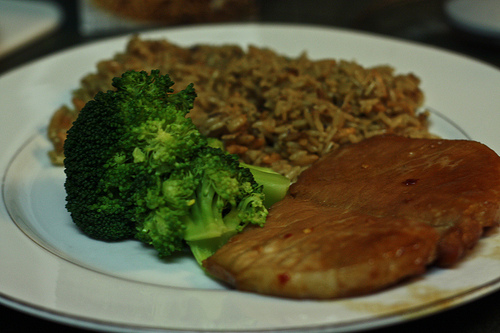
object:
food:
[46, 34, 498, 304]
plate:
[4, 23, 499, 329]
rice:
[47, 33, 442, 183]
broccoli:
[63, 68, 276, 266]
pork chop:
[201, 132, 499, 300]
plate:
[2, 1, 60, 57]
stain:
[329, 286, 459, 322]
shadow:
[128, 234, 152, 251]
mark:
[278, 272, 290, 284]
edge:
[220, 260, 362, 302]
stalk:
[235, 158, 293, 208]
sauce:
[470, 218, 499, 260]